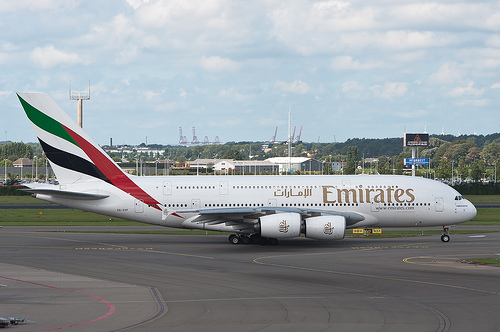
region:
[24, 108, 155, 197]
colorful logo on tail of plane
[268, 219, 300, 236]
gold logo on engine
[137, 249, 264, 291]
gray color on the runway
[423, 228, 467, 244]
black wheel in front of plane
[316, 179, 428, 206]
name on side of plane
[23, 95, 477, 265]
large white plane on runway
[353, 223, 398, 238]
yellow barrier on grass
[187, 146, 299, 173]
large white buildings in the distance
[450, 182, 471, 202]
cockpit on front of plane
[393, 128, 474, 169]
green trees on the mountain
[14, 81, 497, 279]
Plane parked on the cement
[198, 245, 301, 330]
Tracks on the pavement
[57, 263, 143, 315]
Red paint on the cement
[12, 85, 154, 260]
Tail on the plane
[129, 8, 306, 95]
The sky is cloudy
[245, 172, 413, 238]
Windows on side of plane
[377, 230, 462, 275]
Yellow paint on the air strip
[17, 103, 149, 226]
The tail on the plane is colorful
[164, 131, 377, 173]
Buildings in the background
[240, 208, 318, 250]
Jet on side of plane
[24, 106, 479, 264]
A plane on the runway.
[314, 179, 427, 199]
gold writing on the plane.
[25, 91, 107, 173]
The tail is black red and white.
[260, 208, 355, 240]
Two engines on one side of the plane.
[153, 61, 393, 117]
The sky is full with clouds.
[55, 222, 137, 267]
Yellow lines on the runway.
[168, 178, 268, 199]
Windows on the airplane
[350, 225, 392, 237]
yellow cones on the grass.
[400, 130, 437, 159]
Store sign in the parking lot.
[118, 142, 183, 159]
Houses and trees in the background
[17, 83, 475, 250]
a white plane on a run way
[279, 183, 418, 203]
gold writing on a plane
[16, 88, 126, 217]
a white red green and black tail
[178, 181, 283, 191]
windows on a plane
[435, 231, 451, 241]
wheels on a plane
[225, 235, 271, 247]
back wheels on a plane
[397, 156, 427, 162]
a blue and white sign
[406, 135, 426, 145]
a black and white sign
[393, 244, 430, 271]
a double yellow line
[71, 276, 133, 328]
a red single line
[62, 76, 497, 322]
a plane on the ground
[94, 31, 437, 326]
an airplane on the ground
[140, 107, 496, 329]
a white plane on the ground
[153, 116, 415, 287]
a white airplane on the ground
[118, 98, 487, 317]
a passenger plane on the ground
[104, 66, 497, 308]
a passenger airplane on the ground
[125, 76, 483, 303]
a white passenger plane on the ground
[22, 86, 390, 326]
a white passenger airplane on the ground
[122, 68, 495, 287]
a large white plane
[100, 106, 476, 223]
a large white airplane